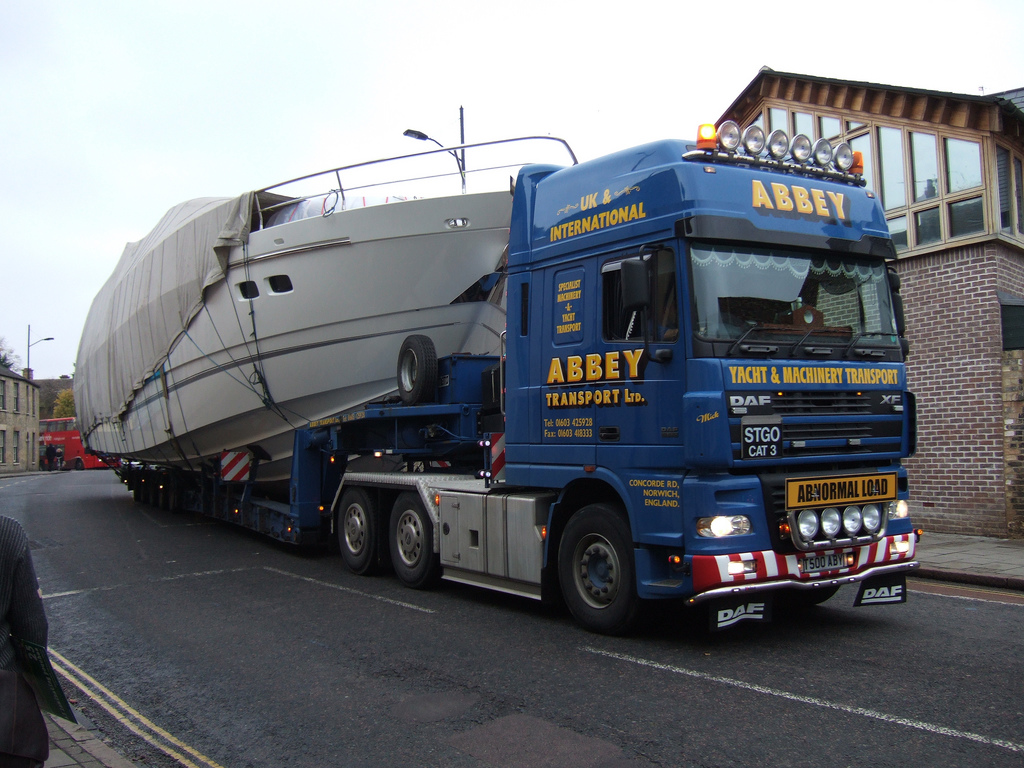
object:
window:
[268, 275, 293, 293]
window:
[914, 206, 942, 246]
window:
[239, 281, 259, 299]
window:
[948, 195, 983, 238]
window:
[909, 132, 939, 202]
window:
[794, 112, 814, 146]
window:
[819, 117, 841, 139]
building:
[2, 363, 41, 476]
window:
[876, 125, 906, 212]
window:
[685, 240, 898, 345]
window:
[767, 108, 786, 136]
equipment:
[72, 136, 578, 481]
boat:
[74, 137, 580, 483]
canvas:
[72, 191, 305, 439]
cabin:
[72, 190, 513, 474]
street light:
[403, 129, 461, 161]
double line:
[47, 646, 230, 768]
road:
[2, 470, 1024, 768]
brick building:
[714, 65, 1024, 540]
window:
[944, 137, 983, 194]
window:
[885, 213, 907, 253]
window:
[846, 121, 865, 133]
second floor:
[714, 65, 1024, 263]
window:
[600, 248, 679, 343]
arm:
[2, 514, 48, 648]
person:
[0, 505, 76, 768]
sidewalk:
[911, 521, 1024, 582]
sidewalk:
[39, 709, 135, 766]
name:
[547, 349, 645, 383]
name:
[751, 180, 846, 219]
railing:
[250, 137, 579, 232]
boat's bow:
[397, 136, 578, 357]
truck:
[74, 121, 922, 633]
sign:
[717, 603, 764, 628]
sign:
[862, 585, 901, 604]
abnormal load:
[785, 473, 898, 511]